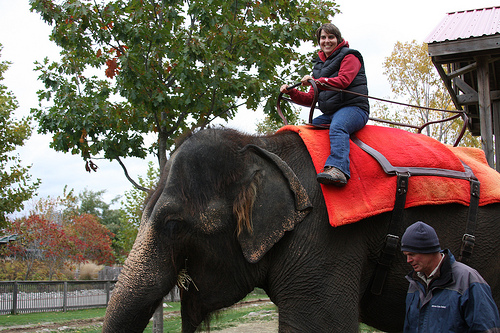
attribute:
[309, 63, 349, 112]
vest — black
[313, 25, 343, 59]
woman — happy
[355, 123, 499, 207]
carpet — red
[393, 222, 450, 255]
cap — gray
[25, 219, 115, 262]
leaves — red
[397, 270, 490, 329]
jacket — blue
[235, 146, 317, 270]
ear — wide, white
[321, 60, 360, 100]
sleeve — red